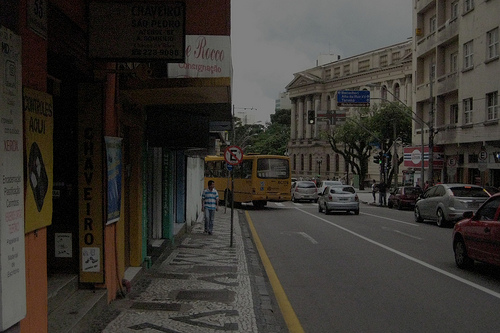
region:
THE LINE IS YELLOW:
[281, 300, 297, 324]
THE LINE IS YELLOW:
[268, 308, 296, 328]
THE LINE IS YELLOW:
[281, 283, 286, 298]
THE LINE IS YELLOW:
[275, 285, 289, 311]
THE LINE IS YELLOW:
[272, 313, 322, 327]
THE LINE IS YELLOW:
[282, 277, 289, 311]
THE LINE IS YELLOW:
[276, 314, 298, 326]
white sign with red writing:
[189, 32, 231, 67]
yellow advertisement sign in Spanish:
[20, 84, 54, 234]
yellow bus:
[202, 151, 296, 211]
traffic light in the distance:
[305, 106, 319, 128]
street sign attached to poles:
[330, 82, 453, 151]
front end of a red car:
[446, 184, 498, 284]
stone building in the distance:
[284, 39, 411, 186]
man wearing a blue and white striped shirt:
[196, 174, 225, 246]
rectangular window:
[458, 92, 478, 134]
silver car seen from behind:
[411, 179, 496, 229]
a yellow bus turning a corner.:
[200, 146, 307, 213]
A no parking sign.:
[201, 131, 260, 262]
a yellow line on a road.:
[236, 206, 303, 331]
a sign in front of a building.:
[7, 60, 72, 239]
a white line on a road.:
[293, 225, 327, 257]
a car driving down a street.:
[318, 166, 365, 225]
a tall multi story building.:
[410, 0, 498, 204]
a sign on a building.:
[161, 31, 239, 86]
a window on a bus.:
[250, 151, 312, 188]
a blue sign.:
[336, 79, 380, 128]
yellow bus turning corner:
[207, 141, 299, 222]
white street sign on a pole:
[201, 128, 276, 212]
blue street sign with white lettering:
[322, 78, 397, 115]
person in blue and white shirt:
[201, 182, 228, 234]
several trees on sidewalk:
[317, 110, 419, 207]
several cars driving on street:
[298, 178, 496, 283]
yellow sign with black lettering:
[8, 75, 86, 220]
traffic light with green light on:
[287, 85, 325, 142]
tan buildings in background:
[294, 58, 482, 198]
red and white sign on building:
[392, 140, 432, 178]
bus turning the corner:
[197, 145, 313, 214]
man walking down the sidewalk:
[192, 167, 226, 247]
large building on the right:
[276, 73, 396, 199]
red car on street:
[424, 175, 498, 285]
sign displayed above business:
[164, 23, 241, 99]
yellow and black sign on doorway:
[15, 82, 67, 246]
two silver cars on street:
[314, 167, 489, 227]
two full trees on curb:
[321, 97, 425, 213]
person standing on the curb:
[362, 174, 380, 211]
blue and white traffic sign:
[326, 74, 390, 124]